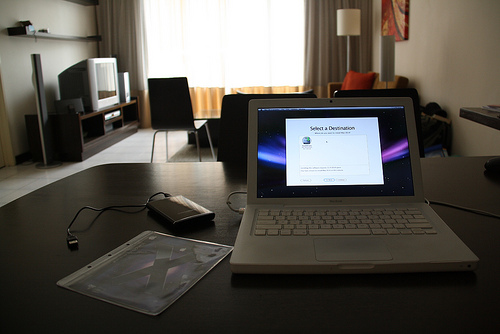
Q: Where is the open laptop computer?
A: On the table.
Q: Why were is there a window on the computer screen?
A: To start the computer program.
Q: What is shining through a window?
A: Sunlight.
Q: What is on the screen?
A: Gray laptop image.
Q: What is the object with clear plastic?
A: Presentation folder.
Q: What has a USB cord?
A: Black external hard drive.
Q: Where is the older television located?
A: On a entertainment center.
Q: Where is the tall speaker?
A: Next to a television.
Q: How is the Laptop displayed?
A: Powered on.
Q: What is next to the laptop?
A: External hard drive and cord.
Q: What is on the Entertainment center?
A: Television and speaker.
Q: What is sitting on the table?
A: A laptop.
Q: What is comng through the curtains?
A: Light.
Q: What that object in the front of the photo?
A: A laptop.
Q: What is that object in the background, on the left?
A: A television.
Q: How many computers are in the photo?
A: One.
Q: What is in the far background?
A: A lamp.